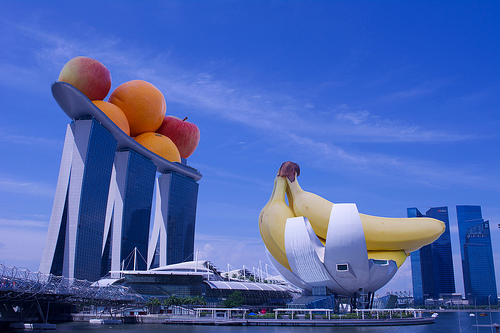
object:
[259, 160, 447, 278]
banana bunch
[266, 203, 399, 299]
building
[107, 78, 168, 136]
orange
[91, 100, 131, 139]
orange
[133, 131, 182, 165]
orange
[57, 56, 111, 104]
apple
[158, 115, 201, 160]
apple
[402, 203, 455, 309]
building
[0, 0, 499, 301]
sky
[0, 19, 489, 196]
cloud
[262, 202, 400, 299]
roof top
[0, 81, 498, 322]
city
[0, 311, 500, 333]
water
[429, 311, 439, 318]
boat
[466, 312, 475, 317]
boat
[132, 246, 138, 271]
pole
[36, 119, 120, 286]
building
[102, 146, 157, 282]
building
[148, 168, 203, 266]
building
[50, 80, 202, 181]
board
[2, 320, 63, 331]
dock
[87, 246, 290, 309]
cruise ship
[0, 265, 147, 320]
bridge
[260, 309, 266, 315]
structure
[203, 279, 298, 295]
arch